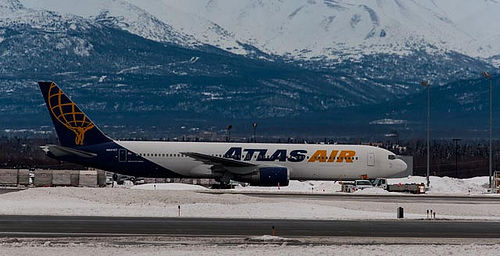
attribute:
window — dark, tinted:
[386, 153, 395, 160]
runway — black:
[0, 213, 498, 239]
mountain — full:
[0, 0, 498, 142]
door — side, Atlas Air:
[363, 150, 381, 170]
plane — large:
[33, 76, 395, 183]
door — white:
[363, 147, 377, 168]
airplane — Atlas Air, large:
[180, 147, 252, 179]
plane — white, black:
[16, 48, 450, 197]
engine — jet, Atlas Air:
[211, 164, 291, 181]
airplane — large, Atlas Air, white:
[13, 77, 406, 191]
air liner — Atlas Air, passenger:
[32, 79, 409, 188]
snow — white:
[8, 167, 497, 213]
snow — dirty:
[119, 182, 308, 216]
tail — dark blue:
[39, 81, 118, 143]